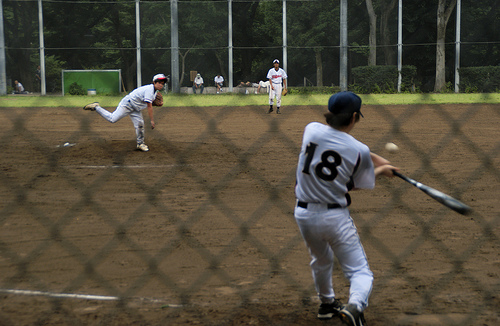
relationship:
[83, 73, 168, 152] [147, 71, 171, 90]
baseball player wearing cap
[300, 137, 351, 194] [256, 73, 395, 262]
number of player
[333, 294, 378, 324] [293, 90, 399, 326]
shoe of a baseball player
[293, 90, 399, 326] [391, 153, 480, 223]
baseball player swinging h bat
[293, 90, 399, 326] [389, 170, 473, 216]
baseball player swinging bat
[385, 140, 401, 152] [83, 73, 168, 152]
baseball thrown by baseball player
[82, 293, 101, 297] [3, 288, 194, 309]
part of line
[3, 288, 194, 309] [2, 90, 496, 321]
line on baseball field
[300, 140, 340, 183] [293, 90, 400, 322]
number of baseball player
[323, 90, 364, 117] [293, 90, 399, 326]
cap of baseball player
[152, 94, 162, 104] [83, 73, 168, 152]
catching mitt by baseball player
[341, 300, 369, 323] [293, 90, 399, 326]
shoe of baseball player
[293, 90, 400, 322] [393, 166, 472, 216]
baseball player swinging bat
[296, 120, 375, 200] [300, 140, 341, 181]
shirt with number eighteen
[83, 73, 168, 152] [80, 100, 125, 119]
baseball player with leg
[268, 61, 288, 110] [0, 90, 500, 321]
baseball player standing in baseball field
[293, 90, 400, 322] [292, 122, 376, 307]
baseball player in uniform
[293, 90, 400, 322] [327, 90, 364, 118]
baseball player wearing cap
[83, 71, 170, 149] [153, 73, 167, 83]
baseball player wearing hat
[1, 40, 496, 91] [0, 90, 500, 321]
fence around baseball field